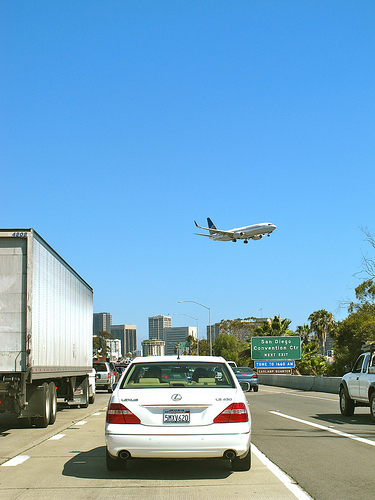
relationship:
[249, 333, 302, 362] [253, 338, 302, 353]
sign says san diego convention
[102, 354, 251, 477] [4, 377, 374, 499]
car on highway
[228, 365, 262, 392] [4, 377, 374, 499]
car on highway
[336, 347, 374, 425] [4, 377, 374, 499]
truck on highway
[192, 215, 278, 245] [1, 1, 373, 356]
airplane in sky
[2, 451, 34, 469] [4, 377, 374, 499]
hash mark on highway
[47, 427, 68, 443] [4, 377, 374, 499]
hash mark on highway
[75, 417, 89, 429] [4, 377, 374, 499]
hash mark on highway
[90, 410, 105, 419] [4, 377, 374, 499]
hash mark on highway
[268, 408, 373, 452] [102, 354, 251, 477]
line right of car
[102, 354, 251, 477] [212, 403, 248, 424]
car has tail light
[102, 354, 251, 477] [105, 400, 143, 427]
car has tail light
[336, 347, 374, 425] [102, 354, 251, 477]
truck to right of car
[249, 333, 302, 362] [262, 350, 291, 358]
sign says next right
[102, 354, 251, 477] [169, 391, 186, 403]
car has lexus symbol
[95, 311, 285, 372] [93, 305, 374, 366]
city on skyline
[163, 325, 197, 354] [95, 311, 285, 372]
building in city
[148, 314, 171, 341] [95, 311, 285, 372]
building in city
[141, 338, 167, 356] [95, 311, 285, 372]
building in city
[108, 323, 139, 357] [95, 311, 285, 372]
building in city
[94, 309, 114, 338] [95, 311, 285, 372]
building in city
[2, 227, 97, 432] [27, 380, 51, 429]
truck has tire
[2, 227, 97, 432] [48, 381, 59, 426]
truck has tire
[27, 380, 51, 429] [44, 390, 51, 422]
tire has rim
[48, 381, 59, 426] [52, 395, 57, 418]
tire has rim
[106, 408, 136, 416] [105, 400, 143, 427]
light in tail light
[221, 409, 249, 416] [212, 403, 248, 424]
light in tail light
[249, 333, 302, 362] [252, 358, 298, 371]
sign on top of street sign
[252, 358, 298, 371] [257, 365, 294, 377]
street sign on top of street sign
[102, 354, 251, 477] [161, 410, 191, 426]
car has license plate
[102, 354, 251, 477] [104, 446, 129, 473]
car has tire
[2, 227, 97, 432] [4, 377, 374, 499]
truck on highway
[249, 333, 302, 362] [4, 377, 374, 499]
sign next to highway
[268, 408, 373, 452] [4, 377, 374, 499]
line on highway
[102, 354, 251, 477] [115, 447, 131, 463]
car has exhaust